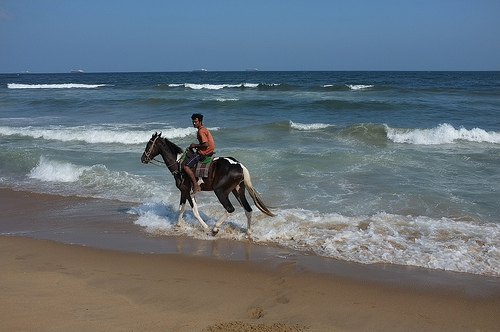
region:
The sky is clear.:
[0, 5, 498, 79]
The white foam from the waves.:
[4, 75, 111, 102]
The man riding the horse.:
[184, 103, 225, 185]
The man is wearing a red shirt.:
[196, 125, 219, 155]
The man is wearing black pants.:
[185, 146, 206, 170]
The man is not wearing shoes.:
[189, 180, 208, 204]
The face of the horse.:
[137, 135, 167, 165]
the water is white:
[346, 213, 431, 258]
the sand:
[284, 281, 346, 324]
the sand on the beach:
[123, 276, 183, 314]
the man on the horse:
[189, 110, 216, 150]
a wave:
[378, 118, 465, 144]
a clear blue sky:
[189, 42, 236, 62]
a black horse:
[134, 138, 184, 175]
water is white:
[42, 153, 98, 183]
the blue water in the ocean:
[391, 85, 428, 116]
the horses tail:
[248, 183, 279, 218]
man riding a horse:
[130, 102, 285, 244]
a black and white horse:
[142, 136, 267, 253]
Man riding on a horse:
[132, 110, 274, 238]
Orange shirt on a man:
[194, 125, 213, 155]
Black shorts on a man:
[182, 153, 202, 166]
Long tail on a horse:
[240, 168, 274, 217]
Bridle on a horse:
[136, 136, 158, 160]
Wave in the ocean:
[249, 115, 499, 147]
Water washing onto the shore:
[279, 209, 499, 287]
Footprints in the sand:
[230, 263, 328, 330]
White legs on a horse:
[177, 197, 205, 231]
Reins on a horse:
[147, 157, 178, 169]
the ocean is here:
[40, 27, 475, 298]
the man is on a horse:
[116, 104, 303, 249]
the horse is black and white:
[142, 125, 299, 245]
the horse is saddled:
[176, 121, 239, 191]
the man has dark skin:
[180, 111, 217, 159]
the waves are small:
[102, 178, 419, 321]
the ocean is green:
[292, 115, 425, 187]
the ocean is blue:
[285, 67, 420, 111]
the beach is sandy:
[136, 249, 495, 324]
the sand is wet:
[272, 238, 487, 291]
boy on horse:
[131, 113, 281, 254]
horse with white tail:
[236, 154, 282, 223]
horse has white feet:
[165, 195, 256, 242]